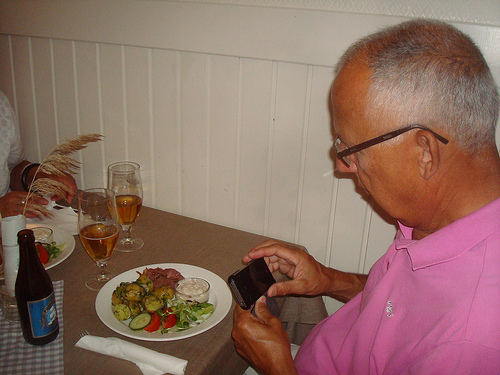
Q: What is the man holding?
A: Phone.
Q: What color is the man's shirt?
A: Pink.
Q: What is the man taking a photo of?
A: Food.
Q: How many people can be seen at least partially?
A: Two.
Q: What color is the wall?
A: White.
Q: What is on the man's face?
A: Glasses.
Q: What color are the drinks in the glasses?
A: Gold.